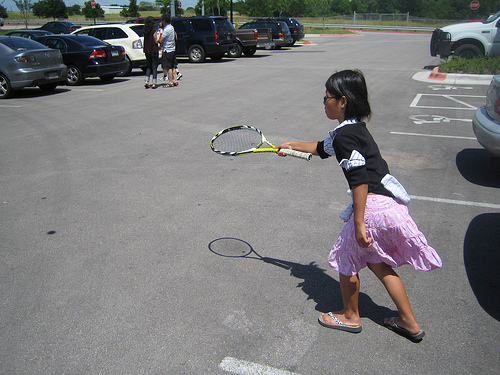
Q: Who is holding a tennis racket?
A: The child in the pink skirt.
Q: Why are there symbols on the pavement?
A: Handicap parking.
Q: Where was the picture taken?
A: Parking lot.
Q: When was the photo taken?
A: Daytime.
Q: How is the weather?
A: Sunny.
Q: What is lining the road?
A: Chain link fence.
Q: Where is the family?
A: Standing near the white car.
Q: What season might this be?
A: Summer.